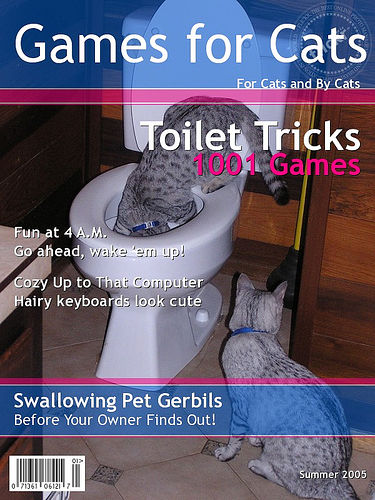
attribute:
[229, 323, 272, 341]
collar — blue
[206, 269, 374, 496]
cat — waiting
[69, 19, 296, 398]
toilet — white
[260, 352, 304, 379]
spots — black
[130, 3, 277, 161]
lid — up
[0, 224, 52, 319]
countertop — marble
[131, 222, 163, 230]
collar — blue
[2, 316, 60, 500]
vanity — wooden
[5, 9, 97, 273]
wall — wooden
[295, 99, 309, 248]
handle — yellow